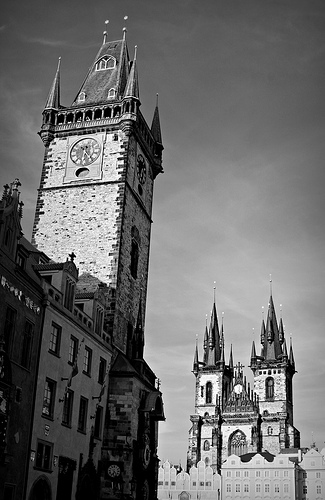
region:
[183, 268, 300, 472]
large cathedral in background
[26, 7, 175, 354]
tower on large cathedral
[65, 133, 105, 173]
clock on cathedral tower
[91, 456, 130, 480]
clock hanging on side of building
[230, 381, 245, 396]
clock on top of cathedral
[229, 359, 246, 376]
cross on top of cathedral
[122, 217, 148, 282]
window on cathedral tower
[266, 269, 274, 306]
spire on top of cathedral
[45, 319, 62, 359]
window on side of cathedral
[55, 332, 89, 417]
flag pole on side of cathedral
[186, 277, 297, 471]
A large and tall building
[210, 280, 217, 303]
An antenna on the top of a building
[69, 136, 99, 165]
A clock on the face of a building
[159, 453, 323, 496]
A row of small buildings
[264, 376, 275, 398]
A arched window on a tall building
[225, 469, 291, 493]
Two rows of windows on a small building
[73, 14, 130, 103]
Tallest section of a building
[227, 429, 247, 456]
Large door on the front of a building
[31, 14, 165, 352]
Very tall tower on top of a smaller building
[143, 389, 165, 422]
A small overhanging eve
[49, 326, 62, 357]
windows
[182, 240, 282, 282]
sky is clear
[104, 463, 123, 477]
a clock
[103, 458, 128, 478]
clock on the building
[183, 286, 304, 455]
a tall building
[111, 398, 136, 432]
bricks on the building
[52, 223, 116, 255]
light on the building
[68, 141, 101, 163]
a clock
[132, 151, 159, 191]
clock on the side of the building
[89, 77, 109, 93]
a roof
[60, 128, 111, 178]
clock face on the tower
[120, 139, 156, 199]
clock face on the tower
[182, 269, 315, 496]
an old large castle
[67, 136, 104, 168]
The clock on the left of the near, tall tower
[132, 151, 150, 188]
The clock on the right of the near, tall tower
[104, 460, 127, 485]
The clock at the bottom of the near tower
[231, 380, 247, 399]
The clock on the far tower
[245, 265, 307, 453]
The right tower of the far church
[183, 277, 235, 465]
The left tower of the far church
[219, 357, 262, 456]
The middle tower of the far church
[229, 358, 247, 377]
The cross atop the far clock tower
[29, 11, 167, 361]
The near clock tower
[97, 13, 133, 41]
The two spiers on the nearest clock tower